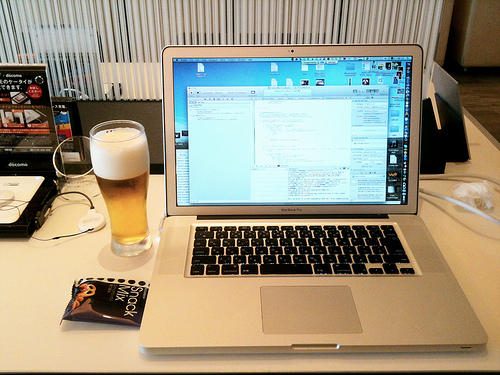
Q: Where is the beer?
A: On the left.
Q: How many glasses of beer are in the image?
A: One.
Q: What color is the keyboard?
A: Black.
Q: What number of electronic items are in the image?
A: One.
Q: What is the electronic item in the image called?
A: A laptop.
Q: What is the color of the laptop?
A: Silver.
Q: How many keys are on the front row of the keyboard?
A: Eleven.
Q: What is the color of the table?
A: White.